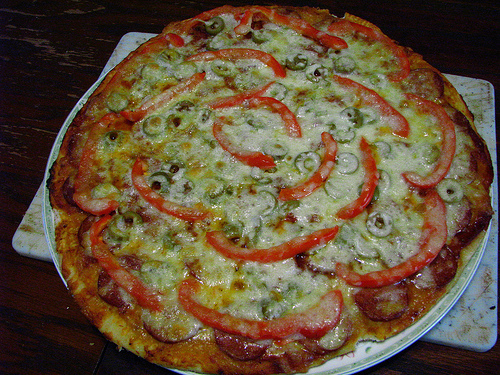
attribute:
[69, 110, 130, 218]
pepper — red, bell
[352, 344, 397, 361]
plate trim — light green, blue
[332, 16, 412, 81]
pepper — red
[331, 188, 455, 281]
pepper — red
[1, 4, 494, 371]
table — wooden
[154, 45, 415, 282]
pizza — red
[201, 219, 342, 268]
pepper — red, bell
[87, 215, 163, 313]
pepper — red, bell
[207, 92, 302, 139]
pepper — red, bell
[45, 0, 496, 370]
pizza — fancy, yummy looking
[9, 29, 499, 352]
board — pizza, white with brown marks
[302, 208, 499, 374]
plate — green and white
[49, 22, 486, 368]
plate — white, blue, green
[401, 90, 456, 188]
bell pepper — red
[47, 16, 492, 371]
cheese — amazing, melted, yummy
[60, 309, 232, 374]
crust — browned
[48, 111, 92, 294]
crust — browned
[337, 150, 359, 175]
olive — black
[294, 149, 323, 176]
olive — black 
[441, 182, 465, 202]
olive — black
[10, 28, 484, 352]
cutting board — dirty, white, brown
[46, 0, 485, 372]
crust — golden brown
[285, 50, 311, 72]
olive — black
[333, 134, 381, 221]
bell pepper — red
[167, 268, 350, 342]
bell pepper — red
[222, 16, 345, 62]
bell pepper — red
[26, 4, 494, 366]
plate — white, serving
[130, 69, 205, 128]
bell pepper — red